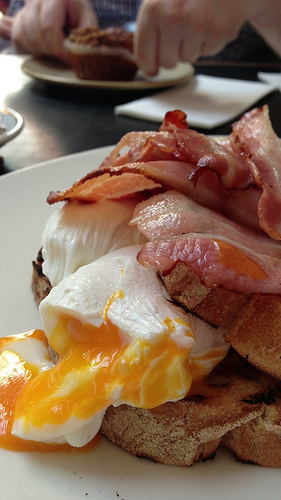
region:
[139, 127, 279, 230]
Stripes of bacon on bread.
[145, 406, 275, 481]
Crust of the bread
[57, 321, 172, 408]
The yolk of the egg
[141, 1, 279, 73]
A hand of a person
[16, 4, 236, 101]
They peel of the wrapper.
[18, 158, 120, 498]
Sandwich on the plate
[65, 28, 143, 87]
A muffin on the plate.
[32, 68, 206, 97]
The plate on the table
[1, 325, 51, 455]
The yolk runs on the plate.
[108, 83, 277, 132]
A white napkin on the table.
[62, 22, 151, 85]
a muffin on a white plate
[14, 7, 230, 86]
a person removing the wrapper of a muffin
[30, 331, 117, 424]
egg yolk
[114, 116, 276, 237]
slices of bacon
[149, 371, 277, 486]
a slice of toasted bread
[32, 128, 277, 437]
bread with poached eggs and bacon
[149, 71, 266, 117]
a white napkin on a table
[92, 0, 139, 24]
person wearing a blue shirt with yellow stripes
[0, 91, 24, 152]
edge of a bowl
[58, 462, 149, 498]
crumbs on a table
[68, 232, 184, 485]
an egg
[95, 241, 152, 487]
an egg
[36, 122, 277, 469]
A bacon and egg sandwich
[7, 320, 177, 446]
The egg yolk is spilling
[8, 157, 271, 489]
White plate under sandwich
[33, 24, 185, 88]
Muffin on a plate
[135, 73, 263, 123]
Napkin by the muffin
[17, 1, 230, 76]
Person about to eat cupcake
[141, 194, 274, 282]
Lightly cooked bacon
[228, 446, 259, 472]
Burnt edge of bread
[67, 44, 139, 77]
Cupcake wrapper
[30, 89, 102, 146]
Black table beneath the plates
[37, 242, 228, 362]
an egg white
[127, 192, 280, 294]
a piece of bacon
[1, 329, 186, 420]
the yolk of an egg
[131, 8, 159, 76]
the finger of a person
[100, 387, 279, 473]
a slice of bread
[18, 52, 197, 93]
a white porcelain plate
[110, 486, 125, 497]
a crumb on the plate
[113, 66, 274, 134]
a white napkin on the table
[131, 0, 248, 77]
the hand of a person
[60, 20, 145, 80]
a brown muffin